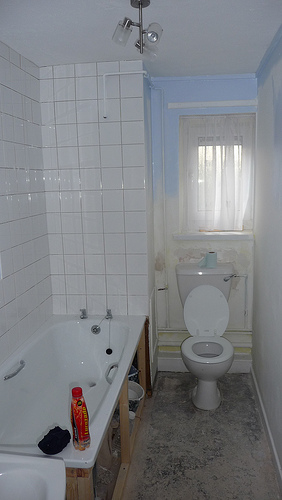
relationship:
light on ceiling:
[110, 1, 163, 54] [1, 1, 280, 76]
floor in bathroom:
[121, 369, 281, 498] [3, 2, 280, 499]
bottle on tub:
[71, 389, 92, 450] [1, 308, 150, 499]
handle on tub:
[104, 357, 117, 385] [1, 308, 150, 499]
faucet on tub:
[77, 308, 112, 322] [1, 308, 150, 499]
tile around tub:
[1, 43, 150, 371] [1, 308, 150, 499]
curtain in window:
[179, 115, 254, 229] [179, 113, 254, 234]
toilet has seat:
[177, 264, 234, 411] [179, 335, 234, 365]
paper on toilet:
[199, 251, 217, 267] [177, 264, 234, 411]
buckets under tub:
[129, 363, 143, 429] [1, 308, 150, 499]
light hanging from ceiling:
[110, 1, 163, 54] [1, 1, 280, 76]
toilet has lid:
[177, 264, 234, 411] [182, 283, 230, 336]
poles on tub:
[67, 317, 150, 499] [1, 308, 150, 499]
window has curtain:
[179, 113, 254, 234] [179, 115, 254, 229]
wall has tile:
[1, 43, 150, 368] [1, 43, 150, 371]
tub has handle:
[1, 308, 150, 499] [104, 357, 117, 385]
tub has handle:
[1, 308, 150, 499] [4, 358, 25, 382]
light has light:
[110, 1, 163, 54] [146, 22, 164, 42]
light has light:
[110, 1, 163, 54] [112, 18, 133, 47]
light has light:
[110, 1, 163, 54] [133, 39, 159, 60]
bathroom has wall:
[3, 2, 280, 499] [1, 43, 150, 368]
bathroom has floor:
[3, 2, 280, 499] [121, 369, 281, 498]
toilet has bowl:
[177, 264, 234, 411] [182, 343, 233, 380]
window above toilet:
[179, 113, 254, 234] [177, 264, 234, 411]